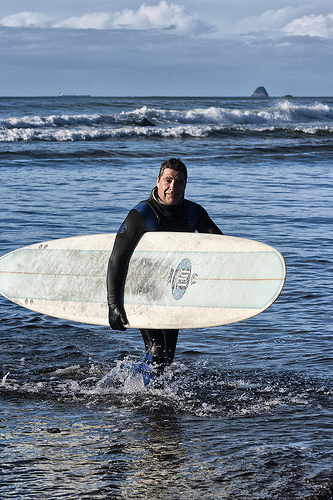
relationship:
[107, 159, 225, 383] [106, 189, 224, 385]
man wearing suit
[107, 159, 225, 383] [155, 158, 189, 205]
man has head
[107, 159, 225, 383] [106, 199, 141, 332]
man has arm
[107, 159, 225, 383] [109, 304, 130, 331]
man has hand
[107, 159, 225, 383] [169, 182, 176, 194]
man has nose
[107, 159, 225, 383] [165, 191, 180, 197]
man has mouth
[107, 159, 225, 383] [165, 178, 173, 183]
man has eye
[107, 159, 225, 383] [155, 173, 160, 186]
man has ear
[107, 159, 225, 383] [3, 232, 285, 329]
man has surfboard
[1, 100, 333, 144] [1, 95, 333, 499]
wave in ocean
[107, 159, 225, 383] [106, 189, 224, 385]
man has suit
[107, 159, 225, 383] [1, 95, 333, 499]
man in ocean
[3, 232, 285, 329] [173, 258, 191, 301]
surfboard has logo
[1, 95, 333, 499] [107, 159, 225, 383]
ocean beneath man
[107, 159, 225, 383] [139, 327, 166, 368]
man has leg